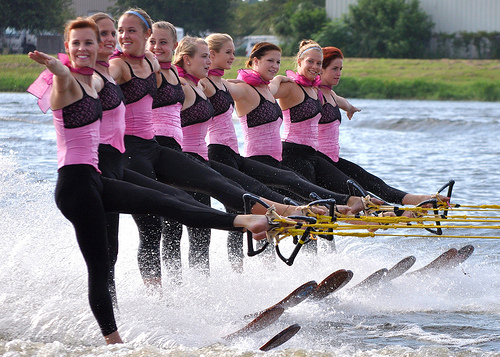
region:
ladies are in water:
[66, 39, 401, 224]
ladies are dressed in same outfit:
[75, 58, 362, 180]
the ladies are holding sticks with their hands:
[271, 188, 496, 240]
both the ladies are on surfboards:
[85, 187, 467, 350]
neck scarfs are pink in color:
[238, 64, 275, 96]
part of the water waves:
[145, 296, 210, 337]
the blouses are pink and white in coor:
[47, 76, 197, 146]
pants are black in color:
[95, 161, 243, 222]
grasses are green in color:
[375, 60, 456, 86]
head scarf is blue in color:
[122, 3, 151, 33]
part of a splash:
[205, 264, 225, 285]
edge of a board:
[273, 316, 297, 347]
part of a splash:
[207, 222, 257, 279]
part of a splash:
[182, 265, 208, 305]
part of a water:
[160, 282, 195, 325]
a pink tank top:
[71, 130, 102, 164]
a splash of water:
[18, 262, 65, 314]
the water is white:
[3, 256, 73, 320]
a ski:
[244, 305, 288, 324]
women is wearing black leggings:
[68, 202, 106, 237]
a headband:
[305, 45, 314, 52]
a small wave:
[406, 109, 441, 136]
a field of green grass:
[363, 59, 483, 84]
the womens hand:
[26, 46, 54, 70]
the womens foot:
[246, 214, 283, 232]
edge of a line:
[328, 269, 350, 285]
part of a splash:
[183, 255, 205, 279]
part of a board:
[289, 268, 304, 308]